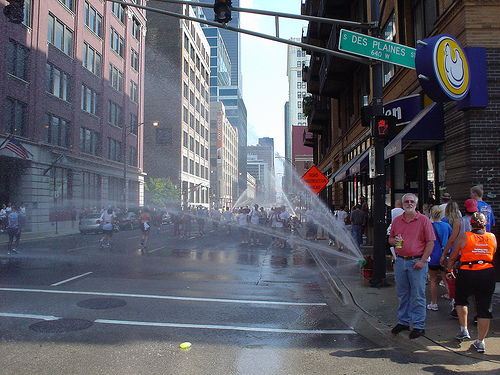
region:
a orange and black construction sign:
[296, 167, 331, 199]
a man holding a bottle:
[381, 197, 421, 271]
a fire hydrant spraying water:
[291, 159, 377, 291]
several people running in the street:
[133, 192, 307, 260]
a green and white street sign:
[323, 30, 412, 72]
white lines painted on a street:
[1, 274, 336, 350]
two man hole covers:
[15, 274, 145, 359]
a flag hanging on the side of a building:
[0, 119, 31, 170]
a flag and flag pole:
[0, 123, 39, 175]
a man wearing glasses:
[400, 185, 420, 212]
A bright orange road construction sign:
[299, 163, 331, 196]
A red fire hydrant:
[351, 247, 381, 290]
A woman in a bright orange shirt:
[442, 211, 497, 353]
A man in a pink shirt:
[384, 192, 436, 341]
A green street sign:
[333, 25, 432, 77]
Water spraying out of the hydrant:
[1, 40, 364, 305]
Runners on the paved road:
[4, 193, 289, 264]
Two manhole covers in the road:
[28, 293, 131, 335]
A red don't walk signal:
[375, 117, 389, 136]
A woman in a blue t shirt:
[426, 200, 454, 314]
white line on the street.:
[147, 318, 204, 332]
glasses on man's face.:
[400, 198, 415, 204]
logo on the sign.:
[439, 46, 461, 88]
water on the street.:
[189, 252, 227, 279]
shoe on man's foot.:
[405, 323, 427, 344]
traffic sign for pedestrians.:
[374, 113, 395, 137]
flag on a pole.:
[5, 138, 32, 163]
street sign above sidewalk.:
[331, 43, 418, 65]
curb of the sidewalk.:
[315, 264, 342, 297]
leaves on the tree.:
[148, 178, 175, 199]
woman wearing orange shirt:
[441, 210, 498, 362]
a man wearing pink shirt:
[355, 187, 496, 363]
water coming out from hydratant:
[240, 156, 375, 289]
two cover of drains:
[24, 282, 146, 353]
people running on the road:
[74, 178, 319, 273]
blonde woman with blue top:
[429, 195, 459, 261]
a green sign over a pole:
[256, 0, 420, 87]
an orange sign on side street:
[296, 158, 336, 261]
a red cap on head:
[461, 193, 483, 218]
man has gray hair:
[381, 188, 437, 260]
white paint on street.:
[135, 316, 168, 328]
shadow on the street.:
[355, 348, 397, 360]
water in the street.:
[240, 251, 277, 265]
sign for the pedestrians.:
[372, 115, 394, 137]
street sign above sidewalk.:
[342, 39, 407, 59]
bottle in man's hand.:
[390, 231, 405, 254]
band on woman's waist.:
[454, 254, 494, 272]